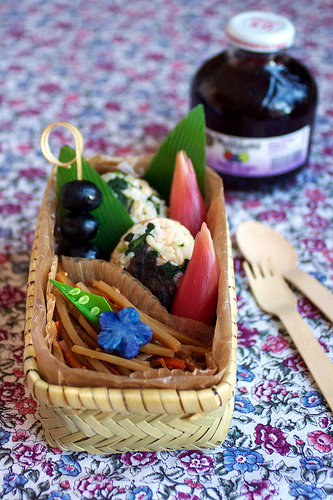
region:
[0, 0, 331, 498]
the tablecloth is flowered pink and blue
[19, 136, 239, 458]
a wicker basket on the tablecloth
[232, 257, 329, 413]
a fork on the tablecloth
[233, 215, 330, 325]
a spoon on the table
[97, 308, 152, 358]
a blue flower in the basket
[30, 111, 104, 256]
olives on a stick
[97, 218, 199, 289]
a rice ball in the basket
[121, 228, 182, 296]
a green leaf on the rice ball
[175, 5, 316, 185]
a bottle on the table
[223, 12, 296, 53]
the bottle lid is white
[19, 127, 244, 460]
a wicker basket on table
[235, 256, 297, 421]
a fork of plastic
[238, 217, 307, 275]
a fork of plastic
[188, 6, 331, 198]
a bottle with juice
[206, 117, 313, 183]
label on a bottle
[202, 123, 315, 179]
label is white and purple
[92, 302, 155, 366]
a blue flower in basket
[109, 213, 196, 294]
a ball with a flower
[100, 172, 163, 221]
a ball with a flower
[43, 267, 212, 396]
brown sticks on basket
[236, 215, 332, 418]
Spoon and fork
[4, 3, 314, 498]
Tablecloth with blue and purple flowered pattern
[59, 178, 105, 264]
Three black olives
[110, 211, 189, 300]
Rice ball wrapped in sea weed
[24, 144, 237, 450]
Lunch basket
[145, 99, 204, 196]
Decorative piece of green plastic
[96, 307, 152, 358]
Blue flower shaped item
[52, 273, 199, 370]
Sliced and pickled vegetables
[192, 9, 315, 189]
Bottle of vitamin drink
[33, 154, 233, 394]
Brown wax paper lining of basket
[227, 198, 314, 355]
a spoon and fork on the table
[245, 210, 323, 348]
the utensils are made of wood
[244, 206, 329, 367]
the utensils are tan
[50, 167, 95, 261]
olives on a stick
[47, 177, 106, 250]
the olives are black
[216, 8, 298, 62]
the bottle cap is white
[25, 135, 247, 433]
the food is in a basket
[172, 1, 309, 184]
a bottle of juice on the table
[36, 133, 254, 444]
a basket of food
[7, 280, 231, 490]
a brown wicker basket of food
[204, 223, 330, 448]
a fork on the table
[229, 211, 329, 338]
a spoon on the table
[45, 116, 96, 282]
black olives on a stick